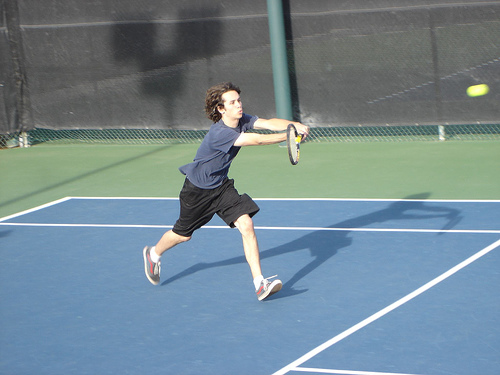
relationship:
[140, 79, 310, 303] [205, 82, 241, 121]
man has hair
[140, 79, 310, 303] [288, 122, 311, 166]
man holding tennis racket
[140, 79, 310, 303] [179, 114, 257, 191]
man wearing t-shirt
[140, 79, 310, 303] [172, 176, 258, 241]
man wearing shorts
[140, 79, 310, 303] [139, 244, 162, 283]
man wearing athletic shoe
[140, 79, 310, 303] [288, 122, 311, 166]
man swinging tennis racket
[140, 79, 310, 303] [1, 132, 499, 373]
man playing on tennis court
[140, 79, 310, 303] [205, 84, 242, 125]
man has head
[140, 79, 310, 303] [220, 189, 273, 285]
man has leg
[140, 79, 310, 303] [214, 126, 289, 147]
man has arm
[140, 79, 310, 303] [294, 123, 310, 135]
man has hand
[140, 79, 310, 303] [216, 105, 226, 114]
man has ear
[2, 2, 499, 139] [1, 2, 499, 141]
fence has net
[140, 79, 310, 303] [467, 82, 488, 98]
man preparing to hit tennis ball